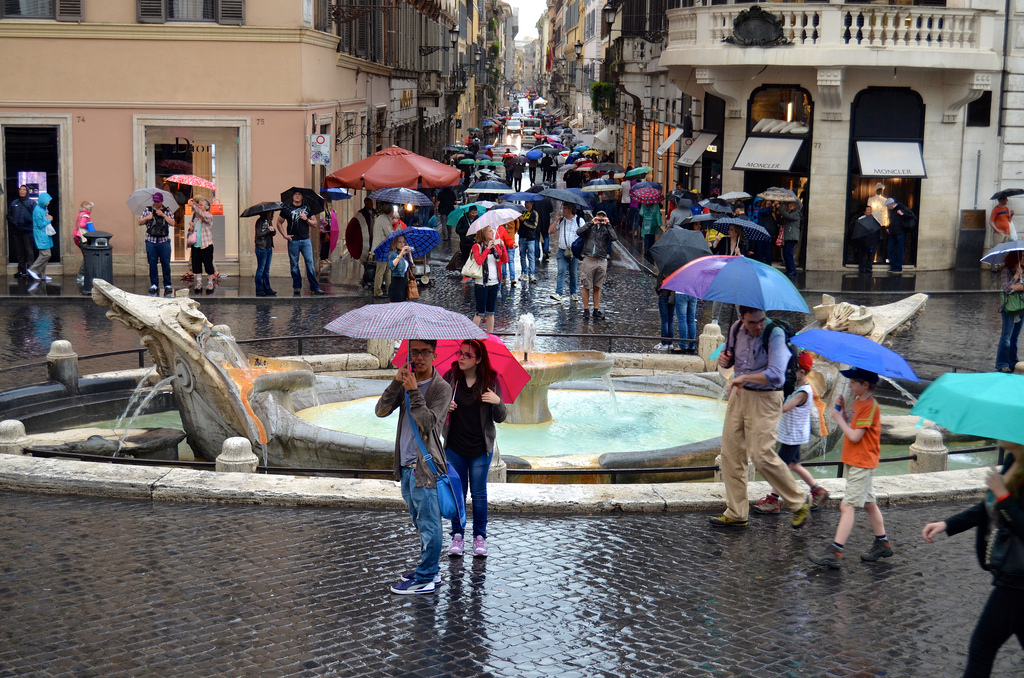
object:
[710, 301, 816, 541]
man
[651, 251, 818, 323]
umbrella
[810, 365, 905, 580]
boy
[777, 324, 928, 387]
umbrella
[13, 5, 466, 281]
building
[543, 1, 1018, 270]
building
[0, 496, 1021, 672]
street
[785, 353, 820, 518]
person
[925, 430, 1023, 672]
person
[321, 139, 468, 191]
umbrella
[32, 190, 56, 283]
person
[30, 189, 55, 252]
jacket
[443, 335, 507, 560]
person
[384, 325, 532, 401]
umbrella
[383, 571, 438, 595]
shoe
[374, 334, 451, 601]
boy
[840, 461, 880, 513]
shorts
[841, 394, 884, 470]
shirt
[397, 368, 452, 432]
arm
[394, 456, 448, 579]
jeans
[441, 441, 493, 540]
jeans